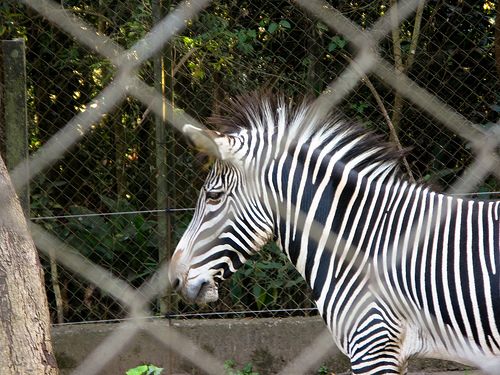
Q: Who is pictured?
A: A zebra.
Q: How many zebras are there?
A: 1.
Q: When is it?
A: Day time.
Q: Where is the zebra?
A: Behind the fence.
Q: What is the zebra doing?
A: Standing.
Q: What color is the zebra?
A: Black and white.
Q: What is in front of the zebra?
A: The fence.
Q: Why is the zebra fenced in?
A: It is at a zoo.